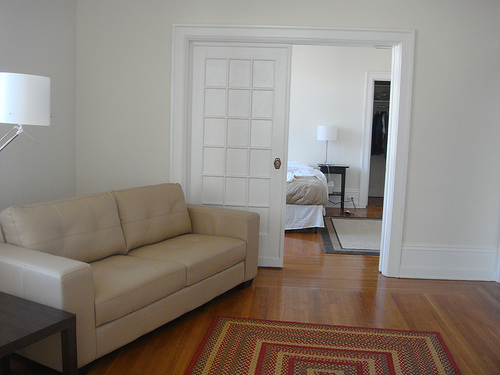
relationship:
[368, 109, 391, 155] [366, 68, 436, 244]
clothes hanging in closet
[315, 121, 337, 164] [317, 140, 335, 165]
lamp with silver base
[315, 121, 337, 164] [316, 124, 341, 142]
lamp and white shade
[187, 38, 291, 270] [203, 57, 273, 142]
door with panes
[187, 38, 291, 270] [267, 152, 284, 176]
door and golden handle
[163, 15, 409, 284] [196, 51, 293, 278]
entryway with open door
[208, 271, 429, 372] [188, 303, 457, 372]
floor with area rug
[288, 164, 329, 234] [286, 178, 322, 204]
bed with comforter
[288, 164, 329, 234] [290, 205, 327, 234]
bed and sheets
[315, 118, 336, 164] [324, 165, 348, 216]
lamp on a table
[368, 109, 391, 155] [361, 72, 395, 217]
clothes in closet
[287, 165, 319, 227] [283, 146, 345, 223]
sheets on bed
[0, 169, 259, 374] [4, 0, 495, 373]
beige couch in living room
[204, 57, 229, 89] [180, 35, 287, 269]
window on door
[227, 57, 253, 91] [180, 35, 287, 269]
window on door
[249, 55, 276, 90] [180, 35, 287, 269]
window on door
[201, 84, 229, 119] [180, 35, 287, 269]
window on door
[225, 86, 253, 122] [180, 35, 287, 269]
window on door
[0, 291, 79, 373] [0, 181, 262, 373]
table next to couch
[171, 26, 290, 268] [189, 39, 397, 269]
door leading to bedroom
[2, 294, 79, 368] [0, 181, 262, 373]
end table by couch